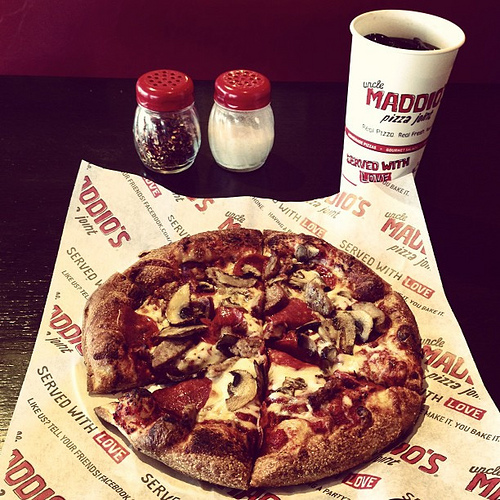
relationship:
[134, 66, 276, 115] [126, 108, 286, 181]
caps on glass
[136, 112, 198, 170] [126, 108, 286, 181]
pepper in glass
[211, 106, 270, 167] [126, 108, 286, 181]
salt in glass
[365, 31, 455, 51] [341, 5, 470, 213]
soda in cup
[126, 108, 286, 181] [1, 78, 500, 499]
glass on table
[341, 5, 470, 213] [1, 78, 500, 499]
cup on table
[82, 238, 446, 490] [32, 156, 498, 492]
pizza on paper